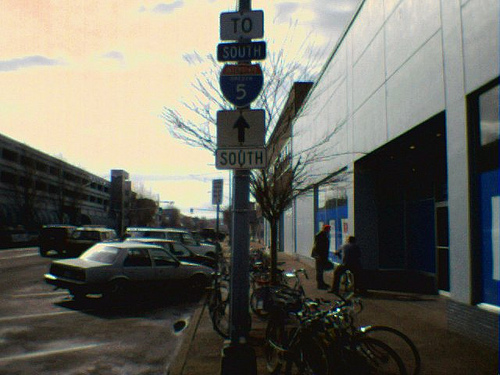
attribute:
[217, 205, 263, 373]
pole — silver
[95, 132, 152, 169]
clouds — white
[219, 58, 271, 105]
sign — street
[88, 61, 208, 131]
clouds — white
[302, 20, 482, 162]
building — white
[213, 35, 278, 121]
sign — blue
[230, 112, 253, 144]
arrow — black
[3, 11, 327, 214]
cloud — white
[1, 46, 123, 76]
clouds — white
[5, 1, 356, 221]
sky — blue